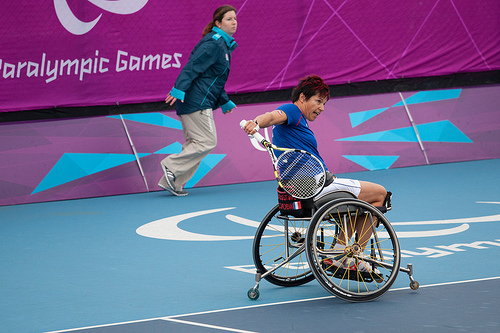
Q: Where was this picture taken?
A: Paralympic Games.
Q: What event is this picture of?
A: Paralympic Games.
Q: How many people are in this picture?
A: Two.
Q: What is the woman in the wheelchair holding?
A: A tennis racquet.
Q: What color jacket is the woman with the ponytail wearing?
A: Blue.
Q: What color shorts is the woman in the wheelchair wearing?
A: White.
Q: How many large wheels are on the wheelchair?
A: Two.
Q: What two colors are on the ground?
A: Blue and white.